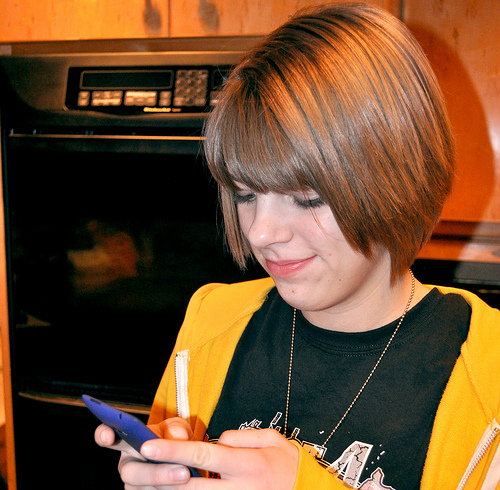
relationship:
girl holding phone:
[152, 52, 424, 346] [74, 381, 210, 477]